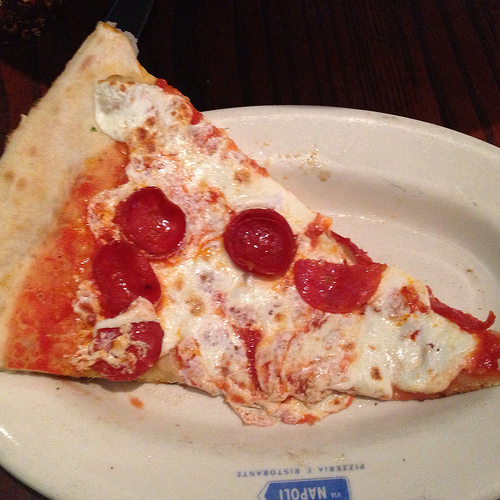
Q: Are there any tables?
A: Yes, there is a table.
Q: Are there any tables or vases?
A: Yes, there is a table.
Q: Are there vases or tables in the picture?
A: Yes, there is a table.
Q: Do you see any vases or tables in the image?
A: Yes, there is a table.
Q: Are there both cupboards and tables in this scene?
A: No, there is a table but no cupboards.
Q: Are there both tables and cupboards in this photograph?
A: No, there is a table but no cupboards.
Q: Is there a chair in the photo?
A: No, there are no chairs.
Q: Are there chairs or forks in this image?
A: No, there are no chairs or forks.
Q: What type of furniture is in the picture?
A: The furniture is a table.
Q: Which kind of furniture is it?
A: The piece of furniture is a table.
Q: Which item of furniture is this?
A: This is a table.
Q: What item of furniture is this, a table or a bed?
A: This is a table.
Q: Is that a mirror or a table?
A: That is a table.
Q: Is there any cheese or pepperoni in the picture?
A: Yes, there is pepperoni.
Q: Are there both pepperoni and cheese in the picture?
A: Yes, there are both pepperoni and cheese.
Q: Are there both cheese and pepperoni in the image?
A: Yes, there are both pepperoni and cheese.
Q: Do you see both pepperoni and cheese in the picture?
A: Yes, there are both pepperoni and cheese.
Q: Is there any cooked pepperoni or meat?
A: Yes, there is cooked pepperoni.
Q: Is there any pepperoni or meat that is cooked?
A: Yes, the pepperoni is cooked.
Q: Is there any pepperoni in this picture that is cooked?
A: Yes, there is cooked pepperoni.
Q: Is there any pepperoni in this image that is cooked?
A: Yes, there is pepperoni that is cooked.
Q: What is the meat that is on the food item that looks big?
A: The meat is pepperoni.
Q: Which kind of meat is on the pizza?
A: The meat is pepperoni.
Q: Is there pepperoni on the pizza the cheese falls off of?
A: Yes, there is pepperoni on the pizza.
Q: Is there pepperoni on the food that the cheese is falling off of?
A: Yes, there is pepperoni on the pizza.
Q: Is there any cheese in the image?
A: Yes, there is cheese.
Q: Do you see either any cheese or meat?
A: Yes, there is cheese.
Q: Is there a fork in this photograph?
A: No, there are no forks.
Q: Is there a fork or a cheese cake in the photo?
A: No, there are no forks or cheesecakes.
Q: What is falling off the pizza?
A: The cheese is falling off the pizza.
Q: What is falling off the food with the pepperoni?
A: The cheese is falling off the pizza.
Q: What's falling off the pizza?
A: The cheese is falling off the pizza.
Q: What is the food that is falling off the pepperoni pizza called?
A: The food is cheese.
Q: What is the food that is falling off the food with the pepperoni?
A: The food is cheese.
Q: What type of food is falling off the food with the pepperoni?
A: The food is cheese.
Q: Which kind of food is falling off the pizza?
A: The food is cheese.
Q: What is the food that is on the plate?
A: The food is cheese.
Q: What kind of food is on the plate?
A: The food is cheese.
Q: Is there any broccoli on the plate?
A: No, there is cheese on the plate.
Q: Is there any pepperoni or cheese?
A: Yes, there is pepperoni.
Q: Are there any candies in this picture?
A: No, there are no candies.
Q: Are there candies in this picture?
A: No, there are no candies.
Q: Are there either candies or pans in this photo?
A: No, there are no candies or pans.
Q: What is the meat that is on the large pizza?
A: The meat is pepperoni.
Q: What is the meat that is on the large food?
A: The meat is pepperoni.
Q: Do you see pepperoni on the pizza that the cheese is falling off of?
A: Yes, there is pepperoni on the pizza.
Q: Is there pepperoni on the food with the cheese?
A: Yes, there is pepperoni on the pizza.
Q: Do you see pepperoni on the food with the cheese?
A: Yes, there is pepperoni on the pizza.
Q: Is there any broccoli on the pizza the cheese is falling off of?
A: No, there is pepperoni on the pizza.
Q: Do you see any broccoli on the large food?
A: No, there is pepperoni on the pizza.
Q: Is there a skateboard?
A: No, there are no skateboards.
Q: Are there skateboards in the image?
A: No, there are no skateboards.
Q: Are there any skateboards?
A: No, there are no skateboards.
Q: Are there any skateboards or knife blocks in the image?
A: No, there are no skateboards or knife blocks.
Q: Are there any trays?
A: No, there are no trays.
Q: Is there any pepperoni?
A: Yes, there is pepperoni.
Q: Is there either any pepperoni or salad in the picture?
A: Yes, there is pepperoni.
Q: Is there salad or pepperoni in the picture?
A: Yes, there is pepperoni.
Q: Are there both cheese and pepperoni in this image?
A: Yes, there are both pepperoni and cheese.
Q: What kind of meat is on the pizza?
A: The meat is pepperoni.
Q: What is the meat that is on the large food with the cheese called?
A: The meat is pepperoni.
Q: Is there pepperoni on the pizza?
A: Yes, there is pepperoni on the pizza.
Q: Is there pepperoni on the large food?
A: Yes, there is pepperoni on the pizza.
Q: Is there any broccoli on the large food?
A: No, there is pepperoni on the pizza.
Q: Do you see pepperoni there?
A: Yes, there is pepperoni.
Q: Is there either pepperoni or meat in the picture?
A: Yes, there is pepperoni.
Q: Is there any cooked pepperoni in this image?
A: Yes, there is cooked pepperoni.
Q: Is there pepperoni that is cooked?
A: Yes, there is pepperoni that is cooked.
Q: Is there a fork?
A: No, there are no forks.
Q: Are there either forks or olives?
A: No, there are no forks or olives.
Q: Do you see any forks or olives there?
A: No, there are no forks or olives.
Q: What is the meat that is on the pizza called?
A: The meat is pepperoni.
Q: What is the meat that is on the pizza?
A: The meat is pepperoni.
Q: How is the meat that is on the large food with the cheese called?
A: The meat is pepperoni.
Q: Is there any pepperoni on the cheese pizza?
A: Yes, there is pepperoni on the pizza.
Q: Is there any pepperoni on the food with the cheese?
A: Yes, there is pepperoni on the pizza.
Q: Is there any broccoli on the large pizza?
A: No, there is pepperoni on the pizza.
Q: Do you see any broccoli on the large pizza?
A: No, there is pepperoni on the pizza.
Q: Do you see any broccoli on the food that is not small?
A: No, there is pepperoni on the pizza.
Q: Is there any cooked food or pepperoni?
A: Yes, there is cooked pepperoni.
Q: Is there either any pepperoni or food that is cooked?
A: Yes, the pepperoni is cooked.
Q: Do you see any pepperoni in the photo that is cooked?
A: Yes, there is cooked pepperoni.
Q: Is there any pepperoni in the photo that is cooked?
A: Yes, there is pepperoni that is cooked.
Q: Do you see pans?
A: No, there are no pans.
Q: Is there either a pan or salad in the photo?
A: No, there are no pans or salad.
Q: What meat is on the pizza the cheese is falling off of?
A: The meat is pepperoni.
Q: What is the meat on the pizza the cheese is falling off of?
A: The meat is pepperoni.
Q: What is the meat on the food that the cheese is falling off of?
A: The meat is pepperoni.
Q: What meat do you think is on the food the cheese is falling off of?
A: The meat is pepperoni.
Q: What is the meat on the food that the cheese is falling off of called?
A: The meat is pepperoni.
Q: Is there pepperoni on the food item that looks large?
A: Yes, there is pepperoni on the pizza.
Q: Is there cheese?
A: Yes, there is cheese.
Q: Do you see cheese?
A: Yes, there is cheese.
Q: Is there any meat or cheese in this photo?
A: Yes, there is cheese.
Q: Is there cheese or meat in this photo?
A: Yes, there is cheese.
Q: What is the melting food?
A: The food is cheese.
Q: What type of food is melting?
A: The food is cheese.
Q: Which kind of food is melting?
A: The food is cheese.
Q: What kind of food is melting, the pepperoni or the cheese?
A: The cheese is melting.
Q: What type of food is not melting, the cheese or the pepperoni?
A: The pepperoni is not melting.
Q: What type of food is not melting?
A: The food is pepperoni.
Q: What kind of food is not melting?
A: The food is pepperoni.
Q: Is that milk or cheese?
A: That is cheese.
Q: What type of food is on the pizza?
A: The food is cheese.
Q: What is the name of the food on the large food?
A: The food is cheese.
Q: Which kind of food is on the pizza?
A: The food is cheese.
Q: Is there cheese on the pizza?
A: Yes, there is cheese on the pizza.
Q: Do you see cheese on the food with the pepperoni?
A: Yes, there is cheese on the pizza.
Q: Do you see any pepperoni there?
A: Yes, there is pepperoni.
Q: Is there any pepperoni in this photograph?
A: Yes, there is pepperoni.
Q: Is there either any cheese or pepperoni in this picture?
A: Yes, there is pepperoni.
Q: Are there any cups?
A: No, there are no cups.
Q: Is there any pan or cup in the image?
A: No, there are no cups or pans.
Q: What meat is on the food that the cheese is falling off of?
A: The meat is pepperoni.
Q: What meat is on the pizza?
A: The meat is pepperoni.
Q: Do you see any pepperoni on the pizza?
A: Yes, there is pepperoni on the pizza.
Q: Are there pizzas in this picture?
A: Yes, there is a pizza.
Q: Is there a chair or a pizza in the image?
A: Yes, there is a pizza.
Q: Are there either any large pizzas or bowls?
A: Yes, there is a large pizza.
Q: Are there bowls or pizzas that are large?
A: Yes, the pizza is large.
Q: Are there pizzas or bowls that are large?
A: Yes, the pizza is large.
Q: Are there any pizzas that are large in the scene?
A: Yes, there is a large pizza.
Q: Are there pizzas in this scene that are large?
A: Yes, there is a pizza that is large.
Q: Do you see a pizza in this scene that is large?
A: Yes, there is a pizza that is large.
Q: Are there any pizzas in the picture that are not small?
A: Yes, there is a large pizza.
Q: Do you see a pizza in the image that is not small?
A: Yes, there is a large pizza.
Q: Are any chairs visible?
A: No, there are no chairs.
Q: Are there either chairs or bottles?
A: No, there are no chairs or bottles.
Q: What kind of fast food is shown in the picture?
A: The fast food is a pizza.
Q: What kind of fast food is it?
A: The food is a pizza.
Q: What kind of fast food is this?
A: This is a pizza.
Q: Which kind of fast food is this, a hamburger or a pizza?
A: This is a pizza.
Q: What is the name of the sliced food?
A: The food is a pizza.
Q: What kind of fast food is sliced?
A: The fast food is a pizza.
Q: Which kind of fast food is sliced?
A: The fast food is a pizza.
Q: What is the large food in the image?
A: The food is a pizza.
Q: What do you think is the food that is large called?
A: The food is a pizza.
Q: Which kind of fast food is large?
A: The fast food is a pizza.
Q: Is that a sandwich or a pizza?
A: That is a pizza.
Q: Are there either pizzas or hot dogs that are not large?
A: No, there is a pizza but it is large.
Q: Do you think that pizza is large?
A: Yes, the pizza is large.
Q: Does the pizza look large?
A: Yes, the pizza is large.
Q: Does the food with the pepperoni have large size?
A: Yes, the pizza is large.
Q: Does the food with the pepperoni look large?
A: Yes, the pizza is large.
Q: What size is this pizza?
A: The pizza is large.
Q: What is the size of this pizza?
A: The pizza is large.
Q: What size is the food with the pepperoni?
A: The pizza is large.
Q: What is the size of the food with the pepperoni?
A: The pizza is large.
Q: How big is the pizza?
A: The pizza is large.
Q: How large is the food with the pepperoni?
A: The pizza is large.